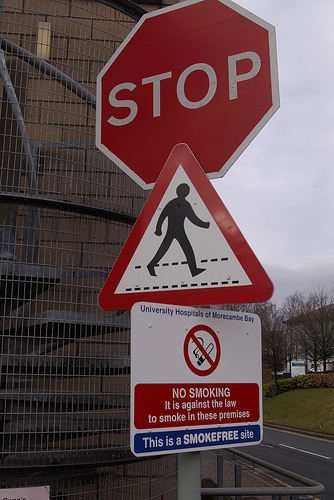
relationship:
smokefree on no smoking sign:
[182, 429, 243, 445] [131, 301, 263, 457]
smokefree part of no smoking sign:
[182, 429, 243, 445] [131, 301, 263, 457]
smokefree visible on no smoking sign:
[182, 429, 243, 445] [131, 301, 263, 457]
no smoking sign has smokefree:
[131, 301, 263, 457] [182, 429, 243, 445]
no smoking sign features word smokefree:
[131, 301, 263, 457] [182, 429, 243, 445]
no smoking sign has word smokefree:
[131, 301, 263, 457] [182, 429, 243, 445]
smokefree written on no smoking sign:
[182, 429, 243, 445] [131, 301, 263, 457]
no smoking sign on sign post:
[131, 301, 263, 457] [177, 452, 202, 500]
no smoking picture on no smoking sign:
[183, 325, 222, 377] [131, 301, 263, 457]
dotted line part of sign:
[125, 278, 243, 295] [96, 141, 275, 314]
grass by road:
[264, 384, 333, 435] [229, 424, 332, 500]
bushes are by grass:
[264, 373, 333, 400] [264, 384, 333, 435]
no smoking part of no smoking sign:
[171, 384, 232, 401] [131, 301, 263, 457]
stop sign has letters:
[96, 1, 280, 194] [109, 49, 261, 127]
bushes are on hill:
[264, 373, 333, 400] [263, 369, 333, 442]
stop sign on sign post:
[96, 1, 280, 194] [177, 452, 202, 500]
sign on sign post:
[96, 141, 275, 314] [177, 452, 202, 500]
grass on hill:
[264, 384, 333, 435] [263, 369, 333, 442]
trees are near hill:
[260, 289, 330, 381] [263, 369, 333, 442]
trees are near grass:
[260, 289, 330, 381] [264, 384, 333, 435]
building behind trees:
[282, 300, 333, 375] [260, 289, 330, 381]